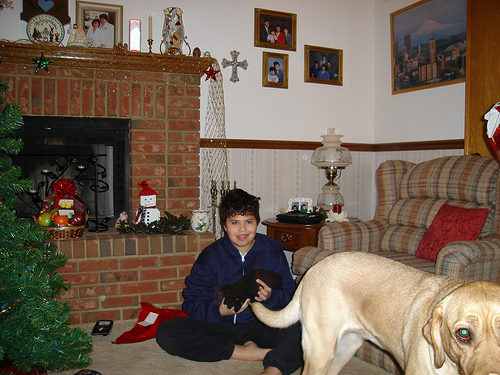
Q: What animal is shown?
A: A dog.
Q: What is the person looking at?
A: The camera.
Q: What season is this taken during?
A: Christmas.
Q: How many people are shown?
A: One.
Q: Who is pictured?
A: A boy.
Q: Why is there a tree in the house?
A: It's a Christmas tree.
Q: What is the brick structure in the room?
A: It's the fireplace.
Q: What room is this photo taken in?
A: The living room.